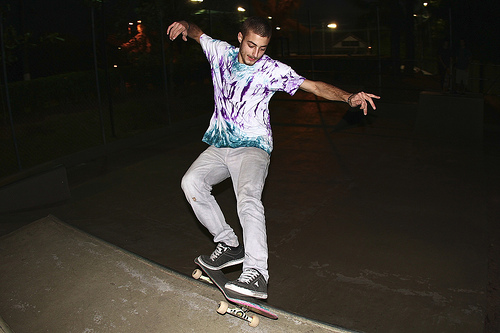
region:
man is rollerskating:
[18, 13, 416, 331]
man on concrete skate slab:
[137, 7, 357, 328]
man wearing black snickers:
[153, 0, 370, 312]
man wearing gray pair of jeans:
[157, 10, 386, 325]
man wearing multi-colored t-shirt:
[161, 13, 354, 168]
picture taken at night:
[6, 1, 496, 246]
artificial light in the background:
[101, 1, 204, 83]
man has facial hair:
[231, 18, 282, 80]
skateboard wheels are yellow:
[163, 233, 297, 330]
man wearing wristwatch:
[316, 77, 386, 127]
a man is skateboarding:
[146, 93, 298, 328]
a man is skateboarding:
[176, 67, 358, 308]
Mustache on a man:
[242, 51, 259, 63]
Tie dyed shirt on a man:
[210, 57, 277, 143]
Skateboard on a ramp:
[196, 255, 263, 330]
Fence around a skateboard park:
[88, 8, 171, 130]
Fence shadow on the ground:
[285, 95, 376, 141]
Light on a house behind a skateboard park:
[321, 20, 341, 35]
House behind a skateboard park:
[302, 34, 392, 60]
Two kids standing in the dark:
[434, 37, 473, 94]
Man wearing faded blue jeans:
[171, 140, 292, 280]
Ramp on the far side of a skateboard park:
[411, 82, 493, 177]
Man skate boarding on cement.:
[152, 15, 384, 326]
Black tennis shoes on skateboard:
[183, 215, 283, 312]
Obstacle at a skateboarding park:
[27, 197, 244, 320]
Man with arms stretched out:
[146, 11, 386, 142]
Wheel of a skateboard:
[203, 290, 253, 330]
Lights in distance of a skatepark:
[127, 25, 378, 62]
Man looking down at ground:
[230, 21, 311, 102]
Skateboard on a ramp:
[173, 240, 299, 320]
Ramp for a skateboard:
[25, 198, 180, 329]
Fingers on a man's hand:
[335, 75, 399, 130]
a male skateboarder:
[155, 14, 385, 327]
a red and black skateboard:
[188, 250, 277, 327]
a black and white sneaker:
[225, 265, 270, 302]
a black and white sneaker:
[196, 234, 243, 274]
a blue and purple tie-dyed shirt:
[195, 29, 303, 151]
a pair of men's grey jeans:
[180, 142, 275, 279]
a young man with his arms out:
[165, 14, 383, 302]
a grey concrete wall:
[12, 214, 374, 331]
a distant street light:
[323, 19, 338, 31]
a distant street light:
[232, 1, 249, 13]